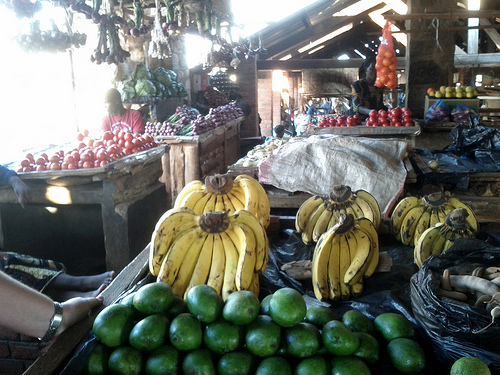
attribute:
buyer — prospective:
[349, 56, 388, 116]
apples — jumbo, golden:
[430, 79, 480, 103]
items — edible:
[430, 262, 497, 332]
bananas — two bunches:
[147, 201, 272, 299]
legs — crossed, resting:
[7, 247, 113, 302]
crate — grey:
[11, 109, 199, 219]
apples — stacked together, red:
[357, 104, 420, 131]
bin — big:
[12, 165, 167, 188]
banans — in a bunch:
[391, 187, 479, 244]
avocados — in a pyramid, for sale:
[86, 280, 428, 374]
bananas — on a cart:
[343, 219, 375, 291]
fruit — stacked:
[174, 178, 258, 363]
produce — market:
[92, 182, 498, 370]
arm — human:
[0, 271, 53, 341]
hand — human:
[48, 294, 105, 342]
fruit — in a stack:
[106, 275, 254, 372]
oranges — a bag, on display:
[368, 37, 408, 104]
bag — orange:
[374, 19, 397, 89]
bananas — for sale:
[125, 152, 307, 349]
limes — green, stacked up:
[111, 283, 341, 373]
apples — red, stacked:
[58, 121, 203, 198]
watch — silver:
[35, 294, 65, 345]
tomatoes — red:
[16, 125, 144, 172]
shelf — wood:
[111, 271, 139, 287]